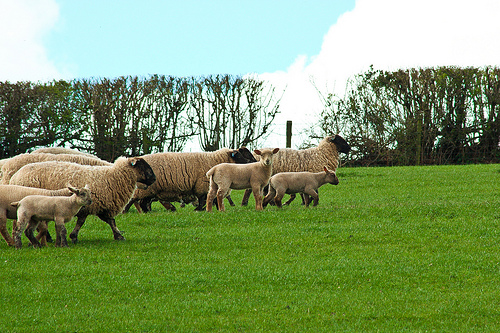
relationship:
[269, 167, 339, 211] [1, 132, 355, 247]
sheep in herd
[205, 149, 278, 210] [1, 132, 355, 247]
sheep in herd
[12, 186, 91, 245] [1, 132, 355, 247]
sheep in herd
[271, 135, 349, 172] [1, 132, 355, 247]
sheep in herd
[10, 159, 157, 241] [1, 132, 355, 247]
sheep in herd